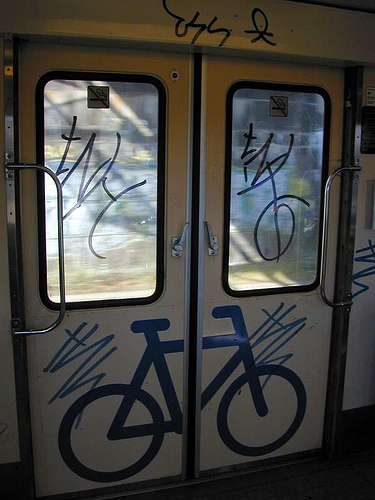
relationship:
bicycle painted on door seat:
[52, 300, 327, 492] [123, 315, 174, 339]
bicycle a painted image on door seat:
[52, 300, 327, 492] [123, 315, 174, 339]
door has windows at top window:
[13, 48, 348, 495] [227, 85, 329, 289]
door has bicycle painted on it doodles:
[10, 36, 353, 498] [43, 320, 116, 429]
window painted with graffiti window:
[41, 77, 156, 300] [227, 85, 329, 289]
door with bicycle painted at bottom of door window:
[10, 36, 353, 498] [227, 85, 329, 289]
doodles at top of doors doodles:
[43, 320, 118, 427] [56, 115, 147, 258]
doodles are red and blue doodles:
[247, 299, 305, 390] [56, 115, 147, 258]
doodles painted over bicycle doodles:
[159, 0, 274, 45] [56, 115, 147, 258]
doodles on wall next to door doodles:
[236, 119, 311, 260] [56, 115, 147, 258]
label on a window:
[265, 94, 290, 117] [41, 77, 156, 300]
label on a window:
[269, 95, 290, 117] [227, 85, 329, 289]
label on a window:
[87, 85, 109, 107] [227, 85, 329, 289]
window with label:
[42, 72, 172, 303] [87, 85, 109, 107]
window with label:
[224, 79, 326, 295] [269, 95, 290, 117]